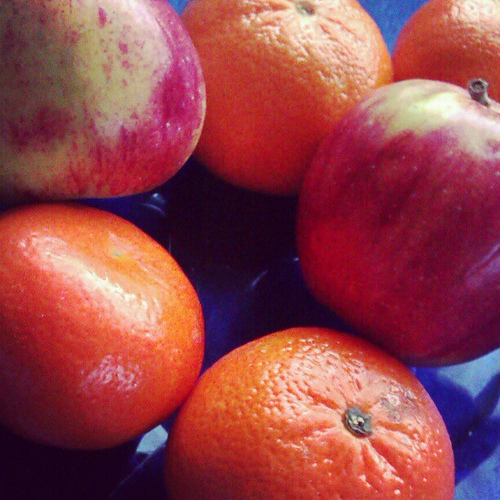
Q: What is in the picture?
A: Fruit.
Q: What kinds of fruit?
A: Apples and oranges.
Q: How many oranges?
A: 4.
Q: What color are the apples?
A: Red.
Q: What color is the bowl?
A: Blue.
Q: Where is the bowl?
A: Under the fruit.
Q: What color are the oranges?
A: Orange.